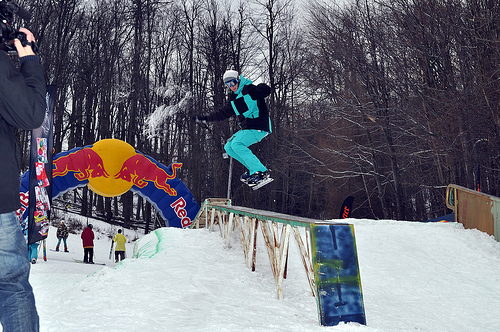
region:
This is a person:
[196, 55, 293, 207]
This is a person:
[104, 218, 144, 281]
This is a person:
[76, 213, 106, 269]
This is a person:
[54, 215, 76, 251]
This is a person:
[1, 4, 59, 328]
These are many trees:
[156, 10, 206, 185]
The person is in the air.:
[190, 64, 280, 199]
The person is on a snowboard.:
[193, 58, 278, 198]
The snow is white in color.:
[82, 287, 198, 329]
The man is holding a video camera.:
[0, 2, 50, 127]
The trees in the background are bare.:
[318, 4, 493, 108]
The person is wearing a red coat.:
[77, 222, 98, 262]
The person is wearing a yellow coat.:
[111, 228, 126, 260]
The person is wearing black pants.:
[80, 244, 95, 263]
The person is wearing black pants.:
[113, 252, 127, 263]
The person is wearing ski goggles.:
[221, 69, 241, 92]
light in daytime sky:
[0, 0, 466, 145]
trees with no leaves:
[4, 0, 498, 222]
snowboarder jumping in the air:
[197, 69, 272, 189]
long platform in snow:
[191, 201, 363, 325]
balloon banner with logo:
[18, 136, 195, 228]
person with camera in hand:
[1, 1, 43, 330]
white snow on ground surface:
[36, 219, 497, 330]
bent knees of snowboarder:
[222, 129, 269, 188]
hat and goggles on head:
[224, 69, 239, 90]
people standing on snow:
[53, 221, 125, 265]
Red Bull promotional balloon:
[15, 137, 203, 229]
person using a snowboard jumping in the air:
[194, 68, 273, 188]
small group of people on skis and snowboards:
[51, 216, 127, 265]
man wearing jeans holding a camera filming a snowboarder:
[1, 6, 46, 330]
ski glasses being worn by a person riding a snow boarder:
[221, 78, 240, 88]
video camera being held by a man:
[0, 0, 36, 52]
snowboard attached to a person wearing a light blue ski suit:
[250, 175, 272, 190]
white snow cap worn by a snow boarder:
[220, 68, 240, 79]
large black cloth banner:
[26, 84, 51, 269]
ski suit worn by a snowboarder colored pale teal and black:
[201, 73, 273, 175]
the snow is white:
[388, 252, 464, 316]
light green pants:
[230, 133, 256, 159]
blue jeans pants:
[3, 252, 35, 310]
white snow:
[139, 275, 191, 322]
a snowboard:
[253, 173, 275, 194]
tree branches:
[120, 47, 167, 78]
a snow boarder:
[194, 66, 292, 192]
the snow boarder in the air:
[209, 70, 299, 196]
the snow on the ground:
[162, 292, 215, 326]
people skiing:
[76, 223, 138, 259]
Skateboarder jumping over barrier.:
[183, 48, 349, 325]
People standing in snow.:
[55, 211, 127, 269]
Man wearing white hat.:
[194, 62, 281, 192]